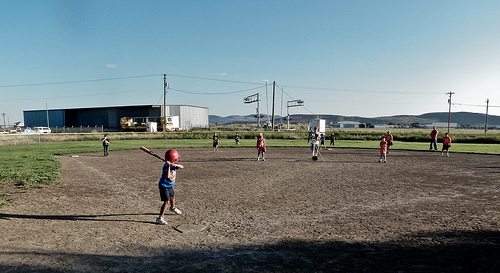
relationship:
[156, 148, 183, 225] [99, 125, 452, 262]
child playing baseball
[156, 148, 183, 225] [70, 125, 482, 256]
child playing baseball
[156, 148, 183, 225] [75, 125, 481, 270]
child playing baseball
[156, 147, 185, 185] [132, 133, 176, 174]
child holding baseball bat